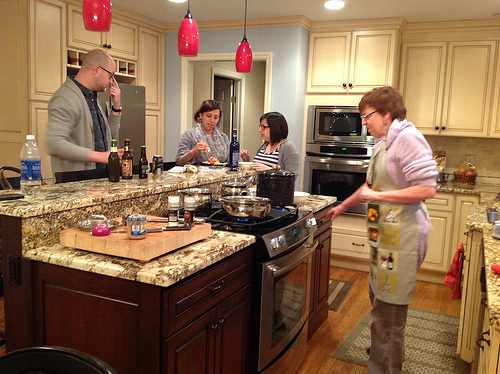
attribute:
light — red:
[177, 12, 200, 58]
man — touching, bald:
[46, 49, 123, 183]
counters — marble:
[2, 163, 338, 289]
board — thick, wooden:
[57, 214, 214, 263]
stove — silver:
[302, 156, 378, 218]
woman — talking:
[329, 87, 437, 373]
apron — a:
[365, 141, 420, 308]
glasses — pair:
[100, 63, 116, 80]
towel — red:
[445, 243, 466, 300]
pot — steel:
[258, 168, 299, 206]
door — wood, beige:
[305, 31, 349, 93]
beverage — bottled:
[104, 137, 150, 184]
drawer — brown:
[156, 243, 264, 340]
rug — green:
[332, 297, 474, 373]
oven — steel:
[253, 209, 319, 373]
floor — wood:
[299, 261, 473, 373]